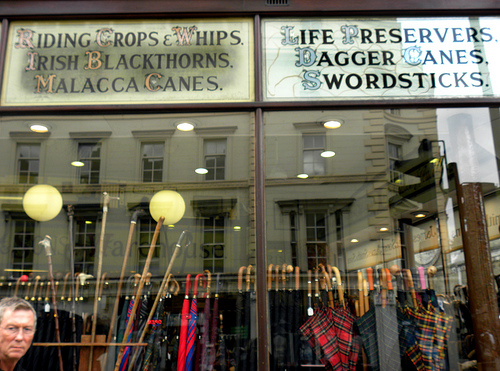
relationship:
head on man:
[1, 296, 37, 369] [2, 292, 35, 361]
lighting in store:
[89, 116, 366, 176] [0, 103, 499, 369]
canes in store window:
[73, 170, 193, 320] [4, 104, 500, 370]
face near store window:
[0, 310, 35, 361] [4, 18, 495, 370]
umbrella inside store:
[404, 264, 453, 369] [6, 1, 493, 368]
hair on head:
[3, 290, 36, 315] [1, 300, 47, 370]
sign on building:
[11, 19, 496, 118] [0, 0, 499, 368]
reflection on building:
[260, 102, 498, 369] [0, 0, 499, 368]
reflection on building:
[0, 109, 258, 368] [0, 0, 499, 368]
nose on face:
[16, 328, 25, 343] [3, 305, 31, 361]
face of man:
[3, 305, 31, 361] [2, 292, 38, 367]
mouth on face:
[8, 341, 29, 348] [0, 310, 35, 361]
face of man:
[0, 310, 35, 361] [1, 287, 40, 369]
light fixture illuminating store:
[25, 123, 188, 230] [13, 30, 484, 349]